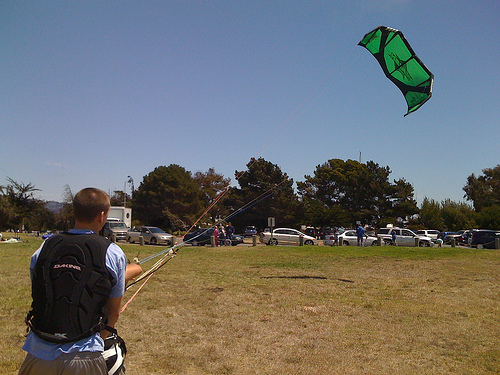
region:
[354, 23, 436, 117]
a green and black kite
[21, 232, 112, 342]
a man wearing a chest protector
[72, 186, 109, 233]
a man's head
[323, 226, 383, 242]
a silver car on the road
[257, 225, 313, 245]
a silver car on the road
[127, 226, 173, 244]
a silver car on the road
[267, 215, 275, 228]
the back of a sign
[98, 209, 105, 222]
ear of a man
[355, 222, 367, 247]
a man in a blue shirt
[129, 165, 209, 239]
a large green tree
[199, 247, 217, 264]
green grass on ground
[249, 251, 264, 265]
green grass on ground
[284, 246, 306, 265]
green grass on ground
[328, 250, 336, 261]
green grass on ground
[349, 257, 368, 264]
green grass on ground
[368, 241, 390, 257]
green grass on ground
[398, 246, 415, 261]
green grass on ground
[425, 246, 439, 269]
green grass on ground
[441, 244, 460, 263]
green grass on ground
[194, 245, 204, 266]
green grass on ground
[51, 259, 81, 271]
The vest has white lettering.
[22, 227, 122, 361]
The boy has a blue shirt on.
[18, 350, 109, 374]
The boy is wearing tan shorts.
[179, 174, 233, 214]
Some kite strings are red.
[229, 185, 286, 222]
Other kite strings are blue.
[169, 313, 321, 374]
Some of the field's grass is dead.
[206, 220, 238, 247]
A family watches the kite fly.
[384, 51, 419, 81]
The kite has a design.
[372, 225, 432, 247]
The truck is silver.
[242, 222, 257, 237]
A blue car is parked by the trees.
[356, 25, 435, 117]
The kite is green.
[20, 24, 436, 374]
The boy is flying a kite.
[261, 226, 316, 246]
A white car parked at the curb.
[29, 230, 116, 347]
The vest is black.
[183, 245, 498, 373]
The field has green grass.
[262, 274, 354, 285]
The kite has a small shadow.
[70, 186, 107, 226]
The boy has blonde hair.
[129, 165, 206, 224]
The tree has green leaves.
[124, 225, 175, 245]
The tan car has an open door.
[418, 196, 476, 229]
Some of the trees are short.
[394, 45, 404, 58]
green material on kite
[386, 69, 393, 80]
black material on kite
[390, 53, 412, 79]
black symbol on kite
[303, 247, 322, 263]
green grass in lawn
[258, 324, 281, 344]
brown grass in lawn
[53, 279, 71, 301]
black bookbag on back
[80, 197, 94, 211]
boy hair is brown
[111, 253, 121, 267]
boy wearing blue shirt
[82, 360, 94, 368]
boy wearing grey pants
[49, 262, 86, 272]
white lettering on bag